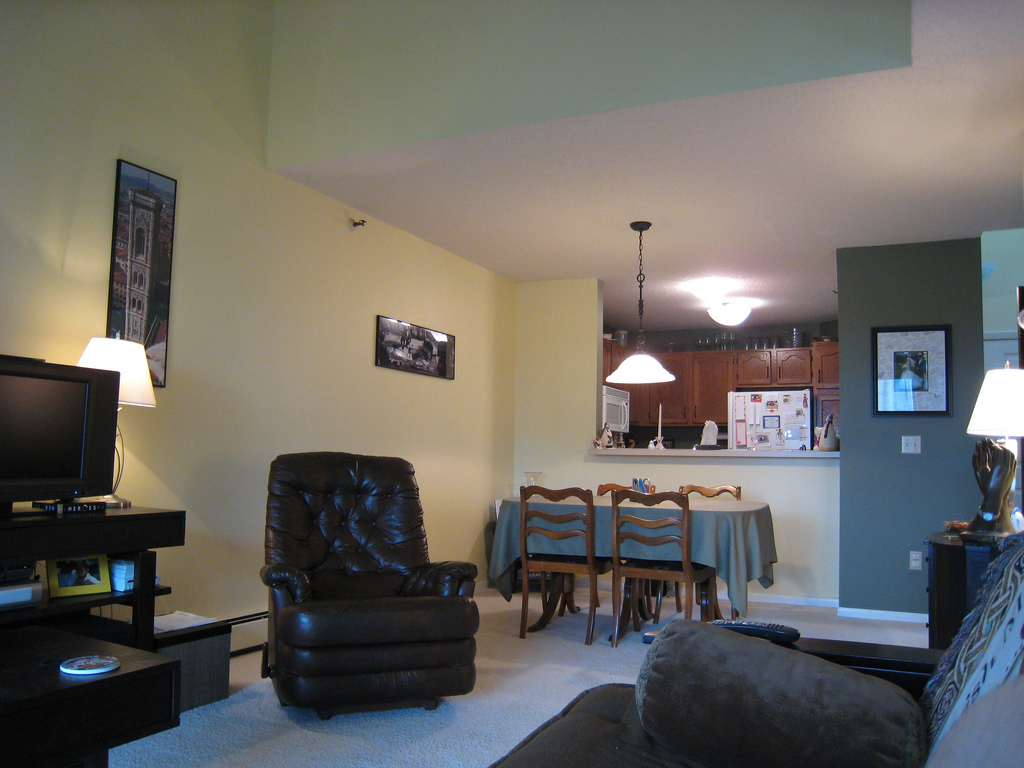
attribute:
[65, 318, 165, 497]
lamp — table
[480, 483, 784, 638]
table — dining, room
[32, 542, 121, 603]
picture — yellow, framed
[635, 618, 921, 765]
tube pillow — tube-shaped, upholstered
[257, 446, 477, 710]
recliner chair — black, leather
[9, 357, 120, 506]
flatscreen tv — black, flat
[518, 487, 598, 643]
wooden chair — brown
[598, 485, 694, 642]
wooden chair — brown